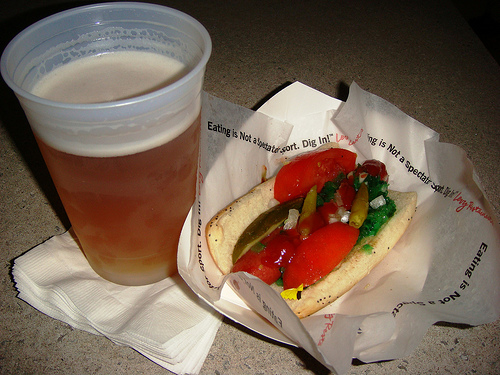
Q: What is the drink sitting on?
A: A napkin.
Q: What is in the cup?
A: Beer.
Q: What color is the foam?
A: White.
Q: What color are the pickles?
A: Green.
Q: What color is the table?
A: White.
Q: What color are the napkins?
A: White.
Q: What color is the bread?
A: Brown.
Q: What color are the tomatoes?
A: Red.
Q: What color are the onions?
A: White.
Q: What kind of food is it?
A: Hot dog.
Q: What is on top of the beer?
A: White foam.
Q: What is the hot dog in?
A: Paper basket.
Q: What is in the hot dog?
A: A pickle.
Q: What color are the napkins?
A: White.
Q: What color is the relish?
A: Green.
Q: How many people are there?
A: None.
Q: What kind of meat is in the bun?
A: Hotdog.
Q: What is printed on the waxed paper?
A: Words.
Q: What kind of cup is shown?
A: Plastic.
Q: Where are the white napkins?
A: Under the cup.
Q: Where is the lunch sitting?
A: Counter.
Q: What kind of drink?
A: Beer.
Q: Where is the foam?
A: Top of beer.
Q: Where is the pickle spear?
A: Top of hotdog.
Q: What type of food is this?
A: Sandwich.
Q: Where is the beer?
A: In plastic cup.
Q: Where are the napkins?
A: Under cup.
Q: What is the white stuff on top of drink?
A: Beer foam.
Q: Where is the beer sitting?
A: On a napkin.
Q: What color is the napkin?
A: White.